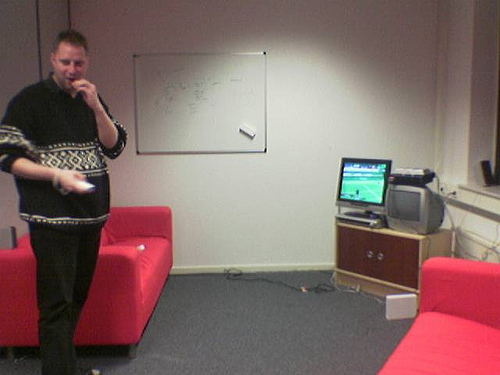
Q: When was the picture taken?
A: Night.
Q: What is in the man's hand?
A: Remote.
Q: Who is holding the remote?
A: A man.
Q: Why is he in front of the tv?
A: Playing a game.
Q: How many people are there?
A: One.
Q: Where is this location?
A: Living room.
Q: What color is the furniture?
A: Red.